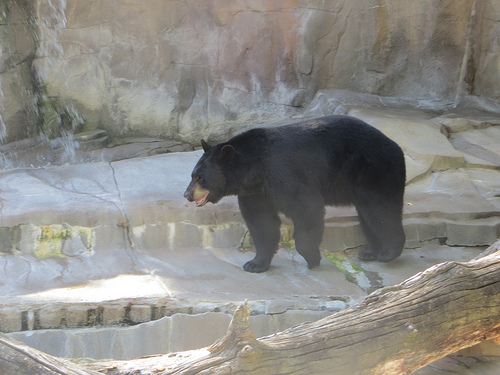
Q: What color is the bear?
A: Black.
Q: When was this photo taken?
A: Daytime.